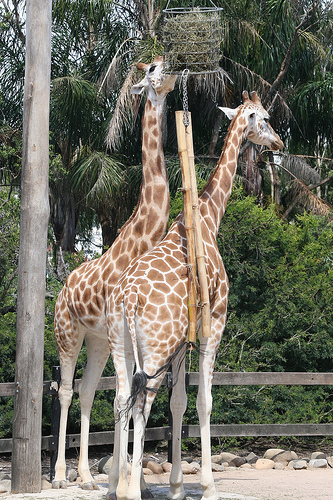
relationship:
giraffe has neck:
[104, 89, 285, 498] [195, 114, 247, 235]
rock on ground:
[263, 447, 286, 460] [0, 439, 331, 498]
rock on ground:
[272, 448, 299, 461] [0, 439, 331, 498]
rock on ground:
[254, 456, 275, 468] [0, 439, 331, 498]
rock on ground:
[292, 458, 307, 468] [0, 439, 331, 498]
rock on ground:
[180, 459, 195, 474] [0, 439, 331, 498]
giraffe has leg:
[104, 89, 285, 498] [198, 296, 222, 498]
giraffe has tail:
[104, 89, 285, 498] [119, 287, 148, 428]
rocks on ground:
[65, 446, 330, 485] [0, 439, 331, 498]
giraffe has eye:
[104, 89, 285, 498] [262, 117, 270, 125]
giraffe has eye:
[51, 53, 189, 498] [147, 61, 156, 73]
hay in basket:
[162, 5, 220, 67] [159, 3, 226, 77]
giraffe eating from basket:
[51, 53, 189, 498] [159, 3, 226, 77]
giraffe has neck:
[51, 53, 189, 498] [133, 93, 172, 247]